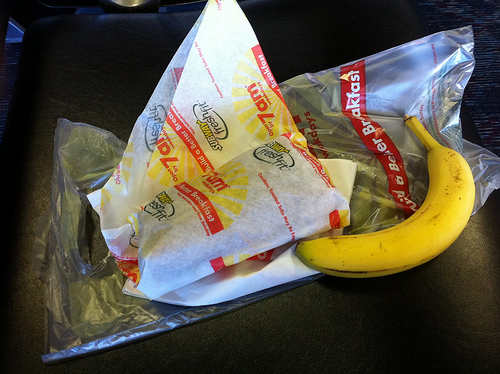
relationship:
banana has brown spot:
[294, 114, 482, 280] [450, 161, 463, 188]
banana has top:
[294, 114, 482, 280] [403, 114, 445, 155]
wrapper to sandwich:
[102, 13, 339, 271] [144, 139, 306, 265]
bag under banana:
[33, 29, 498, 348] [294, 114, 482, 280]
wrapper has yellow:
[102, 13, 339, 271] [178, 151, 207, 192]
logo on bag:
[344, 68, 424, 215] [33, 29, 498, 348]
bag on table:
[33, 29, 498, 348] [16, 17, 494, 366]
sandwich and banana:
[144, 139, 306, 265] [294, 114, 482, 280]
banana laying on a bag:
[294, 114, 482, 280] [33, 29, 498, 348]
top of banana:
[403, 114, 445, 155] [294, 114, 482, 280]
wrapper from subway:
[102, 13, 339, 271] [198, 120, 219, 150]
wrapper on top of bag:
[102, 13, 339, 271] [33, 29, 498, 348]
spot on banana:
[450, 161, 463, 188] [294, 114, 482, 280]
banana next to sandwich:
[294, 114, 482, 280] [144, 139, 306, 265]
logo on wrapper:
[187, 99, 236, 151] [102, 13, 339, 271]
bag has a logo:
[33, 29, 498, 348] [344, 68, 424, 215]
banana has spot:
[294, 114, 482, 280] [450, 161, 463, 188]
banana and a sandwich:
[294, 114, 482, 280] [144, 139, 306, 265]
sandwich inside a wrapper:
[144, 139, 306, 265] [102, 13, 339, 271]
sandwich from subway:
[144, 139, 306, 265] [198, 120, 219, 150]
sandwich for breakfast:
[144, 139, 306, 265] [187, 189, 222, 229]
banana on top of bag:
[294, 114, 482, 280] [33, 29, 498, 348]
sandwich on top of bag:
[144, 139, 306, 265] [33, 29, 498, 348]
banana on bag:
[294, 114, 482, 280] [33, 29, 498, 348]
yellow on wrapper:
[178, 151, 207, 192] [102, 13, 339, 271]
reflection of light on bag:
[364, 58, 483, 132] [33, 29, 498, 348]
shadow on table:
[340, 277, 487, 369] [16, 17, 494, 366]